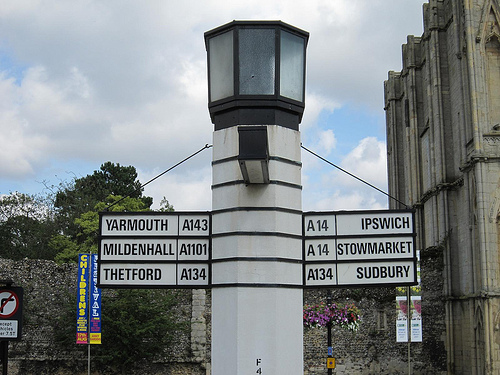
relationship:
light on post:
[196, 19, 311, 130] [212, 124, 310, 375]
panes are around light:
[207, 32, 306, 100] [196, 19, 311, 130]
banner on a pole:
[73, 250, 113, 341] [75, 339, 96, 374]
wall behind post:
[3, 257, 435, 370] [212, 124, 310, 375]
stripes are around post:
[211, 158, 307, 292] [212, 124, 310, 375]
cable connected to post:
[92, 146, 411, 207] [212, 124, 310, 375]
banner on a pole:
[392, 293, 428, 345] [403, 285, 419, 374]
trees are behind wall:
[3, 162, 179, 259] [3, 257, 435, 370]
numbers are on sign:
[181, 216, 338, 293] [94, 211, 421, 283]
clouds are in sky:
[1, 1, 404, 208] [3, 3, 428, 219]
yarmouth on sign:
[96, 214, 182, 235] [94, 211, 421, 283]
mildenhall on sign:
[97, 240, 180, 262] [94, 211, 421, 283]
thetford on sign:
[101, 264, 167, 289] [94, 211, 421, 283]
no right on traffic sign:
[1, 295, 18, 324] [0, 287, 26, 347]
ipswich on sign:
[357, 214, 420, 234] [94, 211, 421, 283]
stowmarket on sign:
[333, 237, 414, 262] [94, 211, 421, 283]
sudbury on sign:
[354, 266, 419, 281] [94, 211, 421, 283]